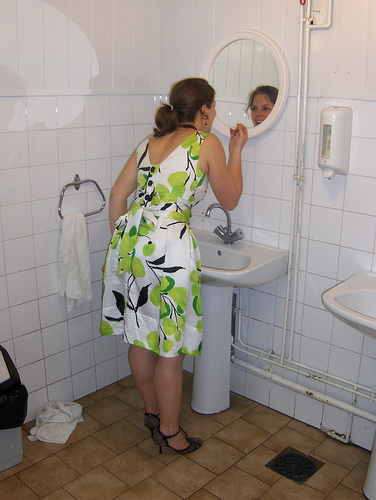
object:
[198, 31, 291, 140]
white frame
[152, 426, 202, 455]
shoes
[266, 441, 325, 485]
drain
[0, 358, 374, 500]
floor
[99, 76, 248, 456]
lady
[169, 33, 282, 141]
make up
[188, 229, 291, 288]
sink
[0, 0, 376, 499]
bathroom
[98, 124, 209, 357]
party dress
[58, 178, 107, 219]
holder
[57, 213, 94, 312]
towel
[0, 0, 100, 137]
spot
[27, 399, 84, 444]
towel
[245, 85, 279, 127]
reflection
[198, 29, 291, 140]
mirror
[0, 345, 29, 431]
handbag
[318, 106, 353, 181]
dispenser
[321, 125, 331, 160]
soap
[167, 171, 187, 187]
green leaves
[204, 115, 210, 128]
earrings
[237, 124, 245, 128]
lipstick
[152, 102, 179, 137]
ponytail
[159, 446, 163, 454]
heel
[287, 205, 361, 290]
shadow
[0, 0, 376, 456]
wall